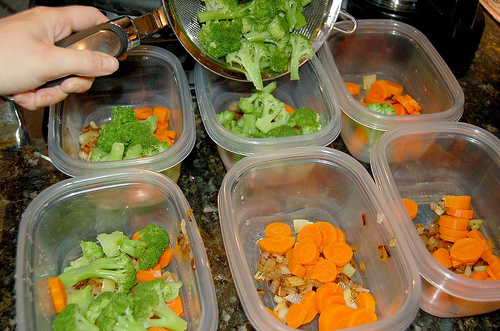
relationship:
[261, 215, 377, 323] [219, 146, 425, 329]
carrots inside of container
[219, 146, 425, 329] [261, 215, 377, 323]
container has carrots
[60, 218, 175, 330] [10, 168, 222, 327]
broccoli in container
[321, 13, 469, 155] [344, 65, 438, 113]
container has carrots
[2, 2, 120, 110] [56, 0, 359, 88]
woman holding strainer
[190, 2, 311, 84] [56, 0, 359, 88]
broccoli in strainer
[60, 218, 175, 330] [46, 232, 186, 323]
broccoli mixed with carrots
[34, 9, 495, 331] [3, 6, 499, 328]
containers are on table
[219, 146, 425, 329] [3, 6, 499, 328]
container on table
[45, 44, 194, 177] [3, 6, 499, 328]
container on table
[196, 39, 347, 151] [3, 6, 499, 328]
container on table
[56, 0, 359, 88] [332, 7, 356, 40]
strainer has a loop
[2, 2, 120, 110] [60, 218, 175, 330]
woman draining broccoli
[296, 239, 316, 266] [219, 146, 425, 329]
carrot in container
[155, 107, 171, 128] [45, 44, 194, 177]
carrot in container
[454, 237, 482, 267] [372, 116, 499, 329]
carrot in container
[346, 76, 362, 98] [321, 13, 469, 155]
carrot in container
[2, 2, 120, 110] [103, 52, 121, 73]
woman has a fingernail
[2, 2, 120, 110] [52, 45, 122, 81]
woman has a thumb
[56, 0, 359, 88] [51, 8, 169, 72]
strainer has a handle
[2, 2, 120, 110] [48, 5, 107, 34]
woman has a finger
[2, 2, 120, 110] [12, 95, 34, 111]
woman has a finger